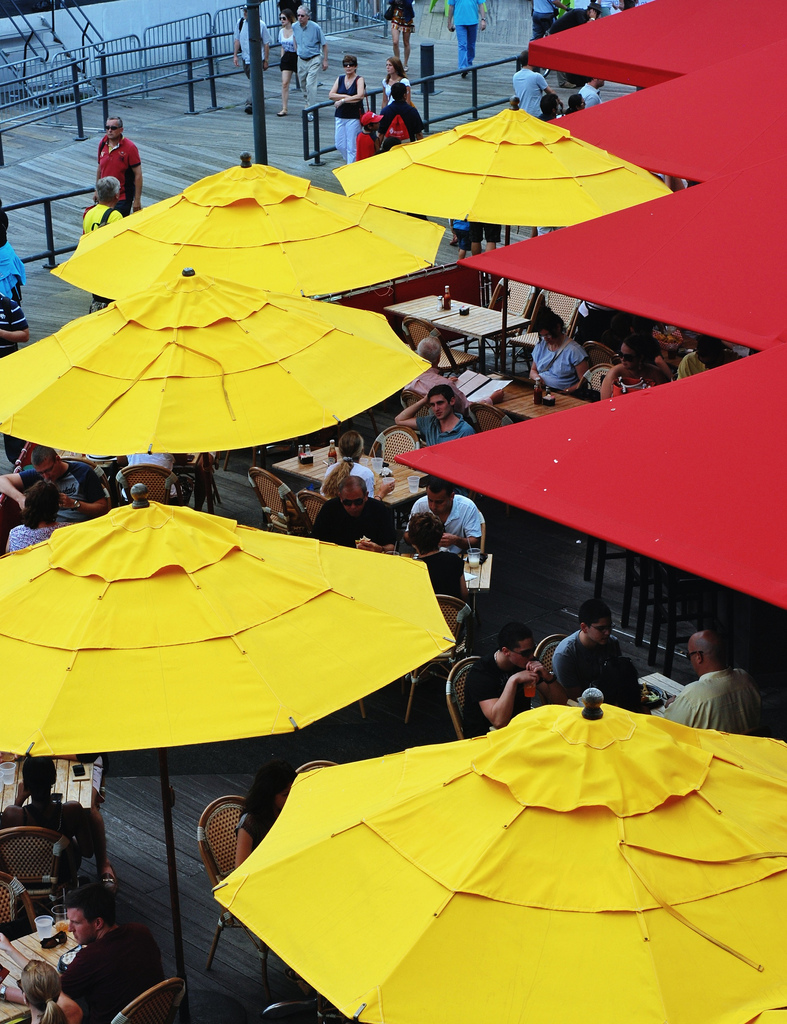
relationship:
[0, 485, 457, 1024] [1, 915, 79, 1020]
umbrella above table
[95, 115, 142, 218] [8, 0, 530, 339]
man walking on pier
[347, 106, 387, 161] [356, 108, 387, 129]
man wearing cap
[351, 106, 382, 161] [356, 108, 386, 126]
man wearing cap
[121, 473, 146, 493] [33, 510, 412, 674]
tip of umbrella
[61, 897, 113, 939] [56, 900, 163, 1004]
head of man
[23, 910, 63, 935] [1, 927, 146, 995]
cup on table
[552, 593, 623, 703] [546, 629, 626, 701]
man wearing shirt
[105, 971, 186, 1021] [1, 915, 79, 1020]
chair sitting at table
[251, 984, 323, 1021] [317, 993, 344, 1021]
chair sitting at table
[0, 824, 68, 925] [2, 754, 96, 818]
chair sitting at table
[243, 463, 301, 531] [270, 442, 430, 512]
chair sitting at table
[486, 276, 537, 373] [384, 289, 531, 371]
chair sitting at table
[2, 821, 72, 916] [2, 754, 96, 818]
chair sitting at table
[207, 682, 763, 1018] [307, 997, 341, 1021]
umbrella covering table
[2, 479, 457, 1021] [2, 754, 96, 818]
umbrella covering table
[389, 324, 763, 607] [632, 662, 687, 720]
umbrella covering table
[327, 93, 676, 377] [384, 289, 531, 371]
umbrella covering table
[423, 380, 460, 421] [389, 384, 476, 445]
head belonging to man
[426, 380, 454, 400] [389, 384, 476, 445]
hair belonging to man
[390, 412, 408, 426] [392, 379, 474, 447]
elbow belonging to man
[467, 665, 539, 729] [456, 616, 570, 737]
arm belonging to man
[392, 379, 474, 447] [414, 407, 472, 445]
man wearing shirt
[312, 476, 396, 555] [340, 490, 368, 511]
man wearing sunglasses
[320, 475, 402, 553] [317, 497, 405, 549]
man wearing a shirt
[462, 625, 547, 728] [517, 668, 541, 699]
man holding cup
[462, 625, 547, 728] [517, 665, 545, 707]
man holding cup